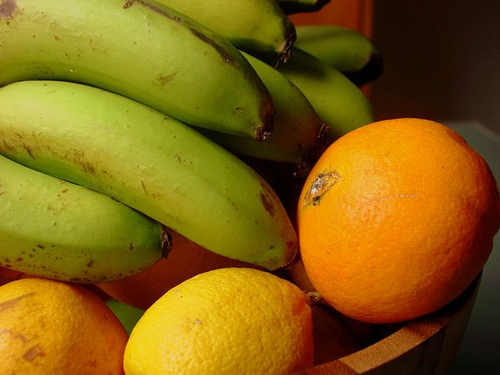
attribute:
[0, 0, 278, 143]
banana — green, unpeeled, unripe, yellow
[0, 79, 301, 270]
banana — green, unripe, yellow green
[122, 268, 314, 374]
lemon — yellow, round, uncut, whole, hidden, ripe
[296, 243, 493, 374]
bowl — brown, wooden, red, wood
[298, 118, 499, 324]
orange — round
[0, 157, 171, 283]
banana — unripe, yellow green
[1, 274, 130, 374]
orange — round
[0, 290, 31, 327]
mark — dark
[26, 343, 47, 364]
mark — dark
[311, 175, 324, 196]
spot — white, brown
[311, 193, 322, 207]
spot — black, brown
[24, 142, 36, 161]
spot — brown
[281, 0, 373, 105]
something — wood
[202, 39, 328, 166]
banana — yellow green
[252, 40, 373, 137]
banana — yellow green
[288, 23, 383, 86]
banana — yellow green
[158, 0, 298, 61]
banana — yellow green